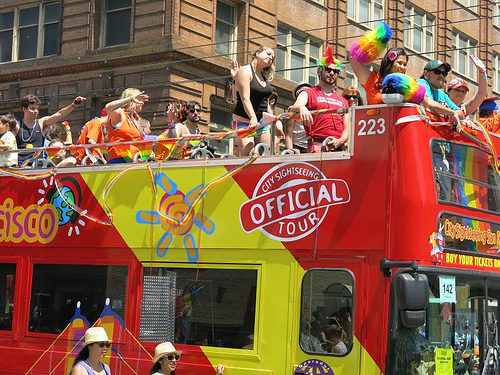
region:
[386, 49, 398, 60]
pink flower in woman's hair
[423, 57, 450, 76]
black hat on man's head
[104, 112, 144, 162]
orange tank top on woman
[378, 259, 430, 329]
rear view mirror on bus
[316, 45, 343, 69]
rainbow mohawk wig on man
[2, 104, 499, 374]
large red bus carrying lots of people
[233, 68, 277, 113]
woman wearing a black t shirt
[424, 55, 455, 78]
man wearing a green hat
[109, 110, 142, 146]
woman wearing a orange t shirt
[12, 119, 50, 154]
Man wearing a black tank top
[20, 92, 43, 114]
man with black hair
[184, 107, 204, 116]
man wearing dark sunglasses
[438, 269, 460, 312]
number 142 posted on the bus window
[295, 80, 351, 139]
man wearing a red t shirt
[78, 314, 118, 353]
woman wearing a brown fedora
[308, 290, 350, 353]
reflection of crowd on the window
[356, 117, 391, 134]
WHITE NUMBERS ON THE BUS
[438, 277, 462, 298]
NUMBER ON THE WINDOW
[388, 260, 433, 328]
MIRROR ON THE SIDE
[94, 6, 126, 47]
WINDOW ON THE BUILDING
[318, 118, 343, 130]
MAN HAS ON A RED SHIRT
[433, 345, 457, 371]
YELLOW SIGN IN THE WINDOW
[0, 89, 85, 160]
party reveler on a double decker bus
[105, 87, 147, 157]
party reveler on a double decker bus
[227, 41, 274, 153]
party reveler on a double decker bus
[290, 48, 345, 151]
party reveler on a double decker bus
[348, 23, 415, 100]
party reveler on a double decker bus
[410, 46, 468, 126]
party reveler on a double decker bus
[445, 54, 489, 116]
party reveler on a double decker bus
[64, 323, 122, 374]
party reveler by a double decker bus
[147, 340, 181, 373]
party reveler by a double decker bus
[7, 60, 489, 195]
people on top of the bus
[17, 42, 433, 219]
people on top of the bus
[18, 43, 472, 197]
people on top of the bus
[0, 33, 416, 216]
people on top of the bus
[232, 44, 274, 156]
woman wearing black top standing on the bus second deck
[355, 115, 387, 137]
the number 223 on the side of the bus